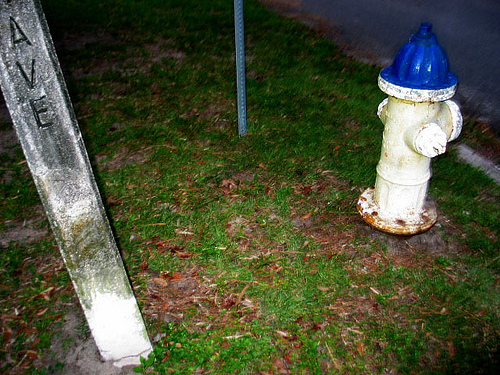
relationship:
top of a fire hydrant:
[374, 22, 463, 87] [352, 19, 461, 236]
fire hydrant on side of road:
[352, 19, 461, 236] [458, 30, 485, 197]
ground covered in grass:
[25, 40, 457, 360] [41, 59, 467, 368]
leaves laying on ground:
[152, 267, 250, 324] [25, 40, 457, 360]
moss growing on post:
[50, 207, 139, 310] [13, 21, 153, 359]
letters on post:
[6, 13, 60, 149] [2, 13, 163, 373]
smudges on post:
[75, 273, 155, 365] [2, 13, 163, 373]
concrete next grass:
[344, 11, 485, 49] [137, 64, 358, 156]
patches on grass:
[155, 271, 260, 325] [113, 154, 371, 372]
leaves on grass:
[170, 284, 237, 327] [81, 109, 441, 372]